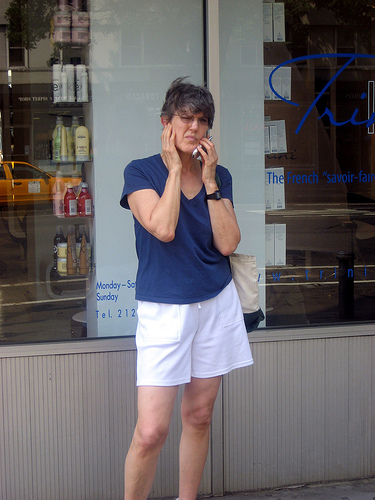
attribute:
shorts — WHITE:
[137, 286, 250, 388]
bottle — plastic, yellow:
[71, 116, 79, 159]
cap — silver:
[72, 114, 77, 125]